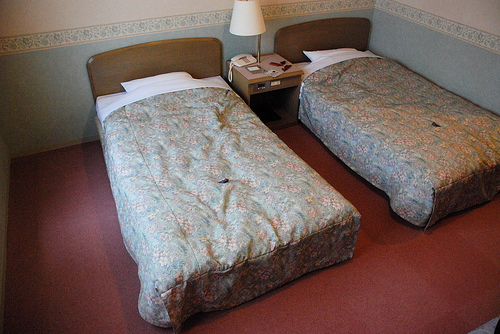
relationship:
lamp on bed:
[230, 0, 267, 63] [91, 34, 361, 331]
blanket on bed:
[96, 80, 362, 328] [91, 34, 361, 331]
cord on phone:
[224, 58, 236, 84] [225, 48, 258, 68]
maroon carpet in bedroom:
[3, 123, 499, 332] [0, 0, 499, 332]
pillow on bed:
[113, 61, 203, 101] [102, 90, 388, 300]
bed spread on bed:
[296, 50, 500, 230] [91, 34, 361, 331]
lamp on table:
[228, 1, 269, 61] [228, 52, 303, 134]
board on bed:
[276, 22, 371, 49] [301, 50, 483, 234]